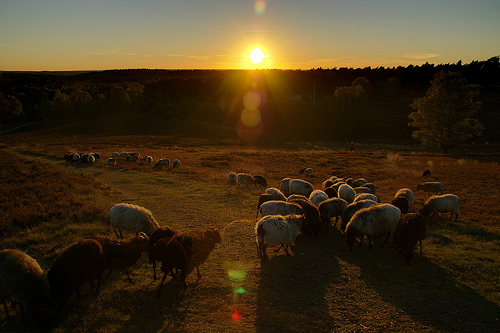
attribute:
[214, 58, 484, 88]
trees — in the distance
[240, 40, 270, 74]
yellow sun — in the sky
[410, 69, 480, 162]
green tree — leafy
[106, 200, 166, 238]
white sheep — grazing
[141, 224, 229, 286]
brown sheep — grazing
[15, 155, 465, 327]
sheep herd — brown and white, very large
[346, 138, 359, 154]
man — standing in the distance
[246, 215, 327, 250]
sheep — white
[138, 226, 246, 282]
sheep — black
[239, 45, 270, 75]
sun — bright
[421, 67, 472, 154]
tree — healthy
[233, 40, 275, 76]
sun — shiny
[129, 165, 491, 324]
sheep — white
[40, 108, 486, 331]
sheep — brown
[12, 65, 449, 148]
trees — small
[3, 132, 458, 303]
field — big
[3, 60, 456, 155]
mountains — large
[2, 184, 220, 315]
sheep — black, white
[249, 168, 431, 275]
sheep — white, brown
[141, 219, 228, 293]
sheep — brown, white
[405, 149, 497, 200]
bush — dry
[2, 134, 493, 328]
grass — lush, green